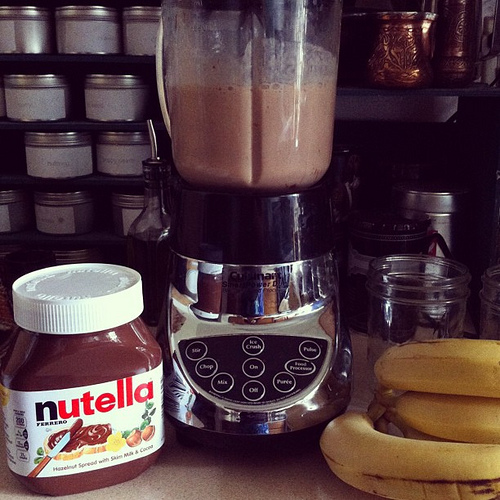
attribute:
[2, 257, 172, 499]
jar — of nutella, new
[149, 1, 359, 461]
blender — cuisinart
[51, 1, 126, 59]
container — small, silver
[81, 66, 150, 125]
container — small, silver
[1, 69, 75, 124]
container — small, silver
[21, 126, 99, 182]
container — small, silver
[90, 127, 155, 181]
container — small, silver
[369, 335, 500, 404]
banana — ripe, yellow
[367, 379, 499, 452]
banana — ripe, yellow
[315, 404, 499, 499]
banana — ripe, yellow